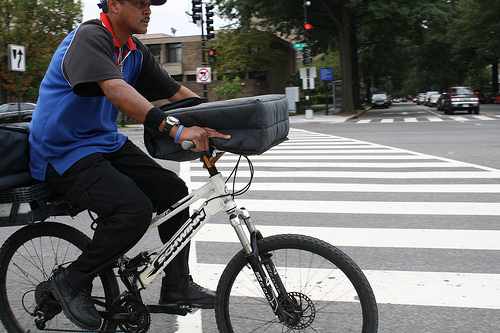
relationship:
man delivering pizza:
[28, 0, 231, 332] [144, 93, 290, 162]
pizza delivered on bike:
[144, 93, 290, 162] [1, 139, 377, 333]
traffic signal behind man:
[192, 0, 203, 24] [28, 0, 231, 332]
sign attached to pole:
[8, 45, 26, 72] [16, 71, 22, 123]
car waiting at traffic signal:
[442, 84, 482, 116] [303, 22, 313, 45]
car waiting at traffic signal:
[437, 92, 447, 110] [192, 0, 203, 24]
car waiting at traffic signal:
[426, 93, 441, 108] [192, 0, 203, 24]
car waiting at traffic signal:
[416, 93, 426, 105] [303, 22, 313, 45]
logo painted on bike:
[147, 209, 207, 278] [1, 139, 377, 333]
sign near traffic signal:
[197, 65, 214, 83] [192, 0, 203, 24]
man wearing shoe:
[28, 0, 231, 332] [47, 268, 103, 331]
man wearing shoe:
[28, 0, 231, 332] [158, 277, 216, 310]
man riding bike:
[28, 0, 231, 332] [1, 139, 377, 333]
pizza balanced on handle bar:
[144, 93, 290, 162] [181, 141, 196, 152]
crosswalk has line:
[173, 124, 499, 333] [190, 223, 500, 251]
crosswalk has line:
[173, 124, 499, 333] [189, 199, 499, 217]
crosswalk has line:
[173, 124, 499, 333] [199, 262, 500, 308]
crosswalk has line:
[173, 124, 499, 333] [191, 180, 500, 193]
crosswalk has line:
[173, 124, 499, 333] [189, 161, 470, 169]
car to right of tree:
[442, 84, 482, 116] [208, 0, 462, 114]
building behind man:
[132, 30, 296, 114] [28, 0, 231, 332]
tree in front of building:
[206, 28, 288, 82] [132, 30, 296, 114]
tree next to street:
[208, 0, 462, 114] [0, 100, 500, 332]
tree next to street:
[442, 0, 500, 95] [0, 100, 500, 332]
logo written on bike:
[147, 209, 207, 278] [1, 139, 377, 333]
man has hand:
[28, 0, 231, 332] [179, 126, 232, 152]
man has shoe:
[28, 0, 231, 332] [47, 268, 103, 331]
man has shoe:
[28, 0, 231, 332] [158, 277, 216, 310]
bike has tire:
[1, 139, 377, 333] [215, 233, 379, 332]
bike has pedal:
[1, 139, 377, 333] [146, 305, 200, 314]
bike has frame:
[1, 139, 377, 333] [112, 174, 302, 333]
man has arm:
[28, 0, 231, 332] [96, 79, 230, 154]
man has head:
[28, 0, 231, 332] [97, 0, 151, 36]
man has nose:
[28, 0, 231, 332] [142, 5, 152, 16]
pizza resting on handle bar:
[144, 93, 290, 162] [181, 141, 196, 152]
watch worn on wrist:
[160, 116, 178, 138] [160, 115, 185, 145]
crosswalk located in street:
[347, 115, 500, 124] [0, 100, 500, 332]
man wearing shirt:
[28, 0, 231, 332] [27, 13, 182, 181]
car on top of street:
[442, 84, 482, 116] [0, 100, 500, 332]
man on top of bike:
[28, 0, 231, 332] [1, 139, 377, 333]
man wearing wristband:
[28, 0, 231, 332] [175, 125, 182, 144]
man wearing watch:
[28, 0, 231, 332] [160, 116, 178, 138]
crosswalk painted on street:
[347, 115, 500, 124] [0, 100, 500, 332]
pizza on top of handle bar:
[144, 93, 290, 162] [181, 141, 196, 152]